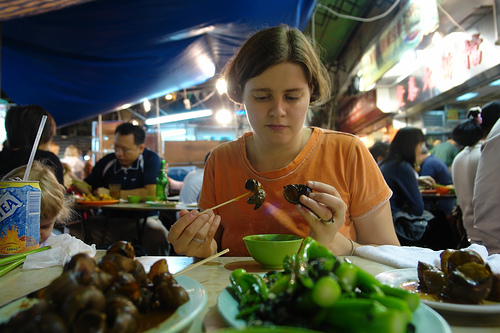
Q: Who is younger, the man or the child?
A: The child is younger than the man.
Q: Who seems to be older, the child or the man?
A: The man is older than the child.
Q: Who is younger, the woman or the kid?
A: The kid is younger than the woman.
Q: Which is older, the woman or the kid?
A: The woman is older than the kid.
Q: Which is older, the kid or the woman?
A: The woman is older than the kid.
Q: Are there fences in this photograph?
A: No, there are no fences.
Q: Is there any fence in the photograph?
A: No, there are no fences.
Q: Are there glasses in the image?
A: No, there are no glasses.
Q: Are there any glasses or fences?
A: No, there are no glasses or fences.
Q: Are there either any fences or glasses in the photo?
A: No, there are no glasses or fences.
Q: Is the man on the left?
A: Yes, the man is on the left of the image.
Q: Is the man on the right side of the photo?
A: No, the man is on the left of the image.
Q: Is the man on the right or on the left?
A: The man is on the left of the image.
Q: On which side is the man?
A: The man is on the left of the image.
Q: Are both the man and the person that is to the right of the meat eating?
A: Yes, both the man and the person are eating.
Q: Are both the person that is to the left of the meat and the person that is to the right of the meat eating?
A: Yes, both the man and the person are eating.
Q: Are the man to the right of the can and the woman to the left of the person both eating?
A: Yes, both the man and the woman are eating.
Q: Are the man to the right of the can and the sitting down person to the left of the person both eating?
A: Yes, both the man and the woman are eating.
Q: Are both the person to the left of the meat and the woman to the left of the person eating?
A: Yes, both the man and the woman are eating.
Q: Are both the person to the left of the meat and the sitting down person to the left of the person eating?
A: Yes, both the man and the woman are eating.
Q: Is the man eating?
A: Yes, the man is eating.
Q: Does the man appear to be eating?
A: Yes, the man is eating.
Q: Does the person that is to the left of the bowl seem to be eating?
A: Yes, the man is eating.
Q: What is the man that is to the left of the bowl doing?
A: The man is eating.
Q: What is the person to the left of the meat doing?
A: The man is eating.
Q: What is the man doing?
A: The man is eating.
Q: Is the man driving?
A: No, the man is eating.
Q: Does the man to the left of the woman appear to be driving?
A: No, the man is eating.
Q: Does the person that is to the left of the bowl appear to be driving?
A: No, the man is eating.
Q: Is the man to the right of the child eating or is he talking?
A: The man is eating.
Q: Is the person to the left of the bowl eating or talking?
A: The man is eating.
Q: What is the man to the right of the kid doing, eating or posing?
A: The man is eating.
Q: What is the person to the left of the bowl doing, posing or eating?
A: The man is eating.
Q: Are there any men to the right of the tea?
A: Yes, there is a man to the right of the tea.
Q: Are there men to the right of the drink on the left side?
A: Yes, there is a man to the right of the tea.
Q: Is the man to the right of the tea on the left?
A: Yes, the man is to the right of the tea.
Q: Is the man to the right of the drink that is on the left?
A: Yes, the man is to the right of the tea.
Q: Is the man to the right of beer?
A: No, the man is to the right of the tea.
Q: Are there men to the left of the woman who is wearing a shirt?
A: Yes, there is a man to the left of the woman.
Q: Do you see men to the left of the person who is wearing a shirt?
A: Yes, there is a man to the left of the woman.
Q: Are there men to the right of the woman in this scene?
A: No, the man is to the left of the woman.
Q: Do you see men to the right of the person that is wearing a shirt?
A: No, the man is to the left of the woman.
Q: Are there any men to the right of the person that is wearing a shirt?
A: No, the man is to the left of the woman.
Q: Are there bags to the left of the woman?
A: No, there is a man to the left of the woman.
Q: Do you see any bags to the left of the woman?
A: No, there is a man to the left of the woman.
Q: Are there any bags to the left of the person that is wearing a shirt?
A: No, there is a man to the left of the woman.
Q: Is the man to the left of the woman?
A: Yes, the man is to the left of the woman.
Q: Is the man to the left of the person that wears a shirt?
A: Yes, the man is to the left of the woman.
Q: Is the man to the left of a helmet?
A: No, the man is to the left of the woman.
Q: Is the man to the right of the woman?
A: No, the man is to the left of the woman.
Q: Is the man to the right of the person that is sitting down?
A: No, the man is to the left of the woman.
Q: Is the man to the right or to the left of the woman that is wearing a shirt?
A: The man is to the left of the woman.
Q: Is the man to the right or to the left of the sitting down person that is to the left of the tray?
A: The man is to the left of the woman.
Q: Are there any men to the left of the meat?
A: Yes, there is a man to the left of the meat.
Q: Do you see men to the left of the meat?
A: Yes, there is a man to the left of the meat.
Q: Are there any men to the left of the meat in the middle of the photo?
A: Yes, there is a man to the left of the meat.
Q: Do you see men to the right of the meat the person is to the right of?
A: No, the man is to the left of the meat.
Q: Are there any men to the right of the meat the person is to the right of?
A: No, the man is to the left of the meat.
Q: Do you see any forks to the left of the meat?
A: No, there is a man to the left of the meat.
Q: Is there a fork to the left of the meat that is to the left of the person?
A: No, there is a man to the left of the meat.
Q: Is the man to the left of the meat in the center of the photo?
A: Yes, the man is to the left of the meat.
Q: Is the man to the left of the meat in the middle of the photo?
A: Yes, the man is to the left of the meat.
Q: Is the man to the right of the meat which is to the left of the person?
A: No, the man is to the left of the meat.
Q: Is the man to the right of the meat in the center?
A: No, the man is to the left of the meat.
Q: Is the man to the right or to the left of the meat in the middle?
A: The man is to the left of the meat.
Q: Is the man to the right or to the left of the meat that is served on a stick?
A: The man is to the left of the meat.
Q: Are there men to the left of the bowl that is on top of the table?
A: Yes, there is a man to the left of the bowl.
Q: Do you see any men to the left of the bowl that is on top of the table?
A: Yes, there is a man to the left of the bowl.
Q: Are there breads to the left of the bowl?
A: No, there is a man to the left of the bowl.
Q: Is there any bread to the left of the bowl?
A: No, there is a man to the left of the bowl.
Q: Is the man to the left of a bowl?
A: Yes, the man is to the left of a bowl.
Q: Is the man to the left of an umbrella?
A: No, the man is to the left of a bowl.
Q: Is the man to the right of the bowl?
A: No, the man is to the left of the bowl.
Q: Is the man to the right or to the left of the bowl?
A: The man is to the left of the bowl.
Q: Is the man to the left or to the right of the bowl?
A: The man is to the left of the bowl.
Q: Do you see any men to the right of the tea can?
A: Yes, there is a man to the right of the can.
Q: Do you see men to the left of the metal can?
A: No, the man is to the right of the can.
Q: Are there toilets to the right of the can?
A: No, there is a man to the right of the can.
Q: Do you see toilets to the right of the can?
A: No, there is a man to the right of the can.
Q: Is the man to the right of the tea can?
A: Yes, the man is to the right of the can.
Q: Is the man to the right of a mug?
A: No, the man is to the right of the can.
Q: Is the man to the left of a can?
A: No, the man is to the right of a can.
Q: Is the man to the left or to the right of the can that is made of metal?
A: The man is to the right of the can.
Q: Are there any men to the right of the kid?
A: Yes, there is a man to the right of the kid.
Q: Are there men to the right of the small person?
A: Yes, there is a man to the right of the kid.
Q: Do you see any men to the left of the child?
A: No, the man is to the right of the child.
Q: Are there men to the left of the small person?
A: No, the man is to the right of the child.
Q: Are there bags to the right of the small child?
A: No, there is a man to the right of the kid.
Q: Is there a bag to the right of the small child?
A: No, there is a man to the right of the kid.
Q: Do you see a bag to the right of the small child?
A: No, there is a man to the right of the kid.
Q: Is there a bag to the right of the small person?
A: No, there is a man to the right of the kid.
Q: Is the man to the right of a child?
A: Yes, the man is to the right of a child.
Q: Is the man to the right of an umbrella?
A: No, the man is to the right of a child.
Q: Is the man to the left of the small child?
A: No, the man is to the right of the child.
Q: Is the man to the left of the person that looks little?
A: No, the man is to the right of the child.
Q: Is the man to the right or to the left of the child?
A: The man is to the right of the child.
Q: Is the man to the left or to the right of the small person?
A: The man is to the right of the child.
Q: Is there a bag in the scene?
A: No, there are no bags.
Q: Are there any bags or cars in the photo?
A: No, there are no bags or cars.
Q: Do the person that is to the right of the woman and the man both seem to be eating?
A: Yes, both the person and the man are eating.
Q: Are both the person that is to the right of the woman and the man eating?
A: Yes, both the person and the man are eating.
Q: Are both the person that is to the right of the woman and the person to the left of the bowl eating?
A: Yes, both the person and the man are eating.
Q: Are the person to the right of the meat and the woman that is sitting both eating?
A: Yes, both the person and the woman are eating.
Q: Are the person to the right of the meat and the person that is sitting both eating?
A: Yes, both the person and the woman are eating.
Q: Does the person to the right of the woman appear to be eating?
A: Yes, the person is eating.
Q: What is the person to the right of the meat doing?
A: The person is eating.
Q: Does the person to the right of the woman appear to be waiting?
A: No, the person is eating.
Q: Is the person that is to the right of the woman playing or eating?
A: The person is eating.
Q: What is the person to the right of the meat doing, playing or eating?
A: The person is eating.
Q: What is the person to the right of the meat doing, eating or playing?
A: The person is eating.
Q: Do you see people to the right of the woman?
A: Yes, there is a person to the right of the woman.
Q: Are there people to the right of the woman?
A: Yes, there is a person to the right of the woman.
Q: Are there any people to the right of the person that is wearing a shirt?
A: Yes, there is a person to the right of the woman.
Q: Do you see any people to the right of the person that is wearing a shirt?
A: Yes, there is a person to the right of the woman.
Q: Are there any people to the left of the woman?
A: No, the person is to the right of the woman.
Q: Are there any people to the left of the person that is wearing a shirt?
A: No, the person is to the right of the woman.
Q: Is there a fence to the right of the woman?
A: No, there is a person to the right of the woman.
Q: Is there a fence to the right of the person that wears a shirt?
A: No, there is a person to the right of the woman.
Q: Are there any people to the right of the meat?
A: Yes, there is a person to the right of the meat.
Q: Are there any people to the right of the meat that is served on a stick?
A: Yes, there is a person to the right of the meat.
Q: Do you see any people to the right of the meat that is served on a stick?
A: Yes, there is a person to the right of the meat.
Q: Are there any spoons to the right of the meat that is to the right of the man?
A: No, there is a person to the right of the meat.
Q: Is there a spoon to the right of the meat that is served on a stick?
A: No, there is a person to the right of the meat.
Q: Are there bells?
A: No, there are no bells.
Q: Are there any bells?
A: No, there are no bells.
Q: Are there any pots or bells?
A: No, there are no bells or pots.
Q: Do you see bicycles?
A: No, there are no bicycles.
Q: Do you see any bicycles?
A: No, there are no bicycles.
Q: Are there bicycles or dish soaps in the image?
A: No, there are no bicycles or dish soaps.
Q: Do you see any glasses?
A: No, there are no glasses.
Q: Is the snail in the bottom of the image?
A: Yes, the snail is in the bottom of the image.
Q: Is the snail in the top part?
A: No, the snail is in the bottom of the image.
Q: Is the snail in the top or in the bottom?
A: The snail is in the bottom of the image.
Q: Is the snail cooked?
A: Yes, the snail is cooked.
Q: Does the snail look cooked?
A: Yes, the snail is cooked.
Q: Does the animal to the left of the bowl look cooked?
A: Yes, the snail is cooked.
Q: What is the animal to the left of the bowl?
A: The animal is a snail.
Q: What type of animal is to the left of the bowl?
A: The animal is a snail.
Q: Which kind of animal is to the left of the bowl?
A: The animal is a snail.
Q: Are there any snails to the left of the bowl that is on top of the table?
A: Yes, there is a snail to the left of the bowl.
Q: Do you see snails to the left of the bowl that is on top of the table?
A: Yes, there is a snail to the left of the bowl.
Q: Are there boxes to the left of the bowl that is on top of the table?
A: No, there is a snail to the left of the bowl.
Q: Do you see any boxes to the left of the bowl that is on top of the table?
A: No, there is a snail to the left of the bowl.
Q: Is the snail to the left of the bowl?
A: Yes, the snail is to the left of the bowl.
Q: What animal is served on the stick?
A: The snail is served on the stick.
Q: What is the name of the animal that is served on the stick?
A: The animal is a snail.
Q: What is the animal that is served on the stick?
A: The animal is a snail.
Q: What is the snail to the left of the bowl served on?
A: The snail is served on a stick.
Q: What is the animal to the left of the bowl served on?
A: The snail is served on a stick.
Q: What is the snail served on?
A: The snail is served on a stick.